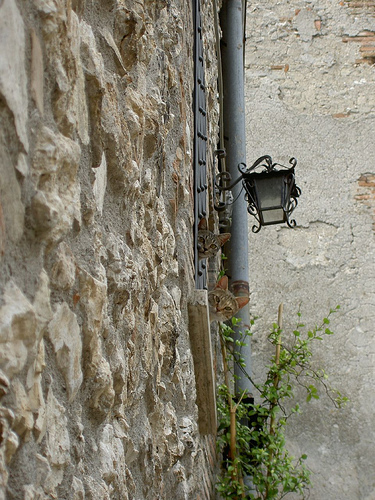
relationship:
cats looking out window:
[186, 217, 235, 307] [201, 57, 255, 101]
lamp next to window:
[260, 161, 313, 219] [201, 57, 255, 101]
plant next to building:
[199, 351, 300, 478] [150, 173, 151, 174]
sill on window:
[190, 30, 223, 64] [201, 57, 255, 101]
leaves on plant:
[267, 319, 322, 345] [199, 351, 300, 478]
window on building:
[201, 57, 255, 101] [150, 173, 151, 174]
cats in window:
[186, 217, 235, 307] [201, 57, 255, 101]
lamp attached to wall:
[260, 161, 313, 219] [271, 12, 366, 73]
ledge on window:
[179, 281, 228, 309] [201, 57, 255, 101]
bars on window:
[207, 9, 261, 47] [201, 57, 255, 101]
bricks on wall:
[343, 3, 372, 55] [271, 12, 366, 73]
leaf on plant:
[265, 318, 286, 354] [199, 351, 300, 478]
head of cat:
[183, 222, 237, 256] [196, 277, 243, 335]